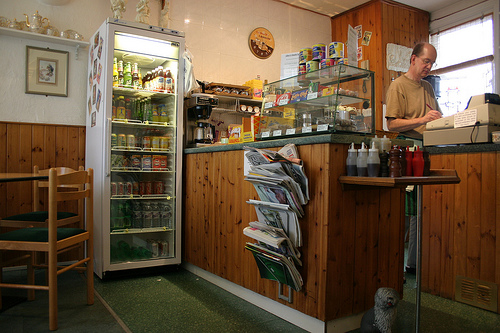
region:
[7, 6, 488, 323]
Photo taken during the day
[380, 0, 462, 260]
Man standing behind a cash register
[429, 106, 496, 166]
Cash register on a counter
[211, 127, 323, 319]
Newspapers on a rack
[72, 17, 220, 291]
Cooler full of drinks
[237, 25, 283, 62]
Clock on the wall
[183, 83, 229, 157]
Coffee maker on the counter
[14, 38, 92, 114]
Framed picture on the wall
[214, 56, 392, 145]
Glass case on the counter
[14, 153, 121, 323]
Two chairs to the left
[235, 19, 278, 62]
A clock hanging on the wall.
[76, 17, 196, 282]
Beverage cooler.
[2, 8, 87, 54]
A decorative tea set on a shelf.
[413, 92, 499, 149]
An electronic cash register.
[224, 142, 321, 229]
Newspapers in a rack.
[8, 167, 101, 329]
Two chairs with green colored seats.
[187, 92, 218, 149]
A coffeemaker.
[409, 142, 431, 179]
A red bottle sitting on a table.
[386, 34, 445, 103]
A man wearing eyeglasses.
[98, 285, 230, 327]
A green colored rug on the floor.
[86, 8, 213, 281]
a white fridge filled with drinks.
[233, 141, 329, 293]
a magazine rack on a counter.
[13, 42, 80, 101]
a framed picture on a wall.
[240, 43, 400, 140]
a display case on a counter.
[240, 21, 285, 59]
a plate posted on a wall.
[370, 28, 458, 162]
a man standing at a cash register.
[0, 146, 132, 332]
a chair under a table.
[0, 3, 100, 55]
a tea set on a shelf.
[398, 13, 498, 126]
a window over a kitchen sink.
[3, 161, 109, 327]
a wooden chair.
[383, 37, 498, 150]
Man at the cash register.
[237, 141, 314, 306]
Newspapers on a rack.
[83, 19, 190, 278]
Drinks in the cooler.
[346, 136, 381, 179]
Bottles of syrup.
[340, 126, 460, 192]
A table with condiment.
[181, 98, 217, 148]
Coffee maker on the counter.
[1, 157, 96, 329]
Table and two chairs.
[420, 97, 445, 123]
Hand holding a pencil.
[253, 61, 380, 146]
Glass display case.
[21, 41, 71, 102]
Drawing on the wall.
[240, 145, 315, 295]
newspapers and magazines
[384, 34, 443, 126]
a man writing with a pencil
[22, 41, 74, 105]
a picture in a brown frame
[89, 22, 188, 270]
a refrigerator full of drinks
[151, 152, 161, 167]
an orange can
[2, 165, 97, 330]
wooden chairs at a table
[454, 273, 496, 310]
a vent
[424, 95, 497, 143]
a white cash register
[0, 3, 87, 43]
a tea set on a shelf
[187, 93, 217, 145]
a silver coffee maker